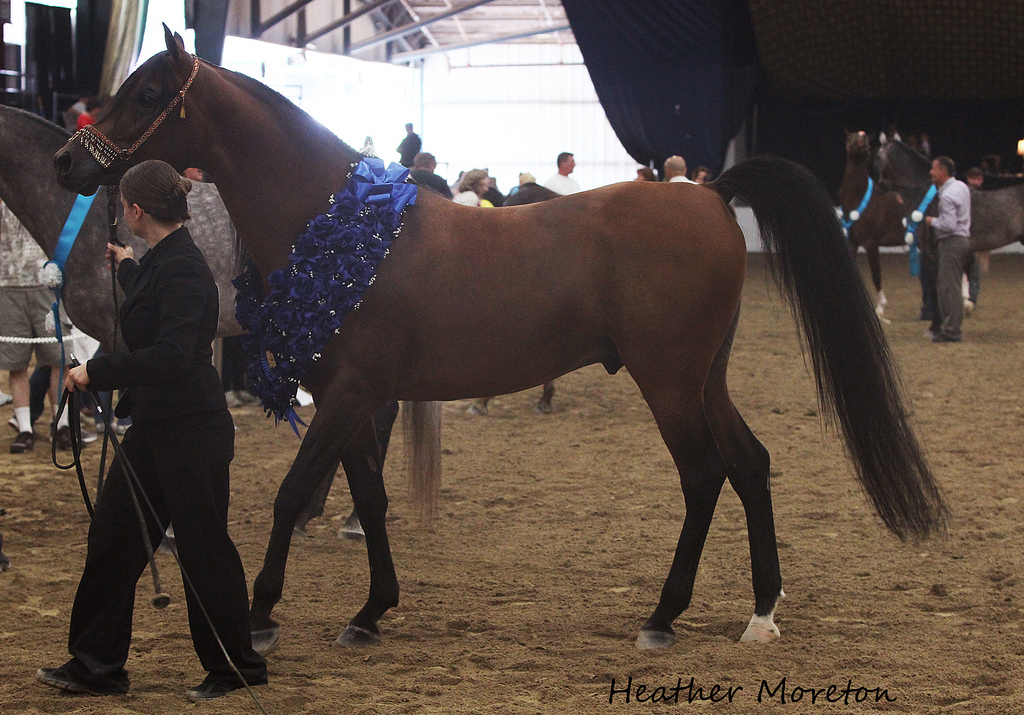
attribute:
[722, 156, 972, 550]
tail — black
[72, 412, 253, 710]
pants — black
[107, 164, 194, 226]
hair — dark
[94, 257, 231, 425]
jacket — black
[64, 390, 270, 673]
pants — black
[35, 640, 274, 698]
shoes — black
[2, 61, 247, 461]
horse — Brown 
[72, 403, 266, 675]
pants — gray 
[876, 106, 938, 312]
horse — brown 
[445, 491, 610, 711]
dirt — brown 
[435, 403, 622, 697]
dirt — brown 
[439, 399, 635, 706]
dirt — brown 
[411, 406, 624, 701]
dirt — brown 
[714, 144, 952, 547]
tail — black, long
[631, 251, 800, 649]
legs — back